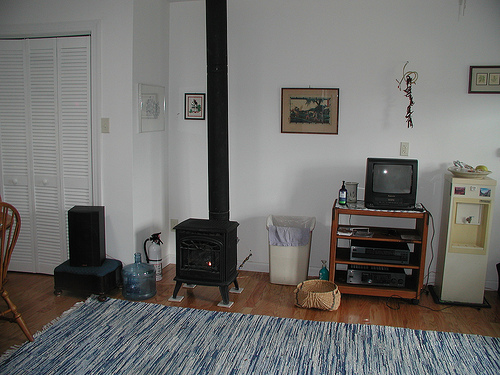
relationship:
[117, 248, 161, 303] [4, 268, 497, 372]
gallon on floor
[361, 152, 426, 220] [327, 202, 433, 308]
television on stand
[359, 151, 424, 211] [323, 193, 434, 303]
tv on stool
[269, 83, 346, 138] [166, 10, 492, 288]
picture on wall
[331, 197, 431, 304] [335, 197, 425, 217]
cabinet has shelf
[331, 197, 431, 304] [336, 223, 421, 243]
cabinet has shelf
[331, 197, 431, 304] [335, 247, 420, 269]
cabinet has shelf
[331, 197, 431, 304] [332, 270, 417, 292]
cabinet has shelf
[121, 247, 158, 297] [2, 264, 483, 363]
waterbottle on floor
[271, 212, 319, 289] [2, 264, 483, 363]
trash can on floor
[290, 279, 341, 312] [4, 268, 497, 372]
basket on floor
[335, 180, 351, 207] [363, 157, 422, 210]
bottle next to tv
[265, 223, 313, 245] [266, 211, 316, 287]
towel folded over trashcan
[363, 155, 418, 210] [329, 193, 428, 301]
t.v. on stand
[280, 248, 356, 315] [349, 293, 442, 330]
basket on floor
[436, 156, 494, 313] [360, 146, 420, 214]
water machine to right of t.v.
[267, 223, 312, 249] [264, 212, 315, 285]
washcloth hanging on trash can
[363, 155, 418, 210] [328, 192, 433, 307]
t.v. on stand